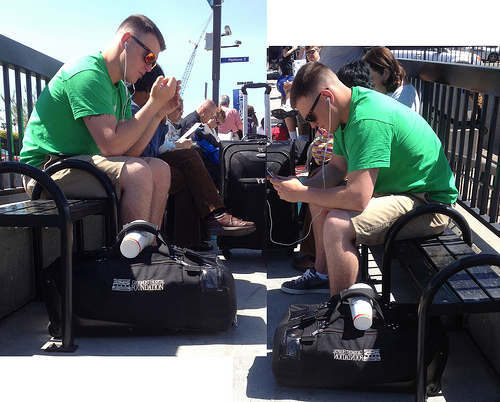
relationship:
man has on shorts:
[267, 59, 457, 321] [348, 185, 455, 247]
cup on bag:
[118, 219, 155, 258] [40, 220, 237, 336]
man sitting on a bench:
[268, 59, 458, 311] [359, 202, 498, 399]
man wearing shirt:
[268, 59, 458, 311] [322, 86, 463, 203]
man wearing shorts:
[268, 59, 458, 311] [340, 192, 452, 245]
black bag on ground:
[249, 288, 458, 400] [0, 216, 444, 400]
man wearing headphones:
[268, 59, 458, 311] [266, 92, 331, 249]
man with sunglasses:
[106, 45, 183, 86] [132, 38, 158, 69]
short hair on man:
[291, 58, 332, 110] [295, 64, 444, 337]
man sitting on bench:
[267, 59, 457, 321] [337, 168, 498, 400]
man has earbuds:
[19, 11, 182, 249] [120, 32, 130, 77]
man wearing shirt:
[19, 11, 182, 249] [20, 50, 138, 167]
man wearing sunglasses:
[19, 11, 182, 249] [121, 30, 160, 69]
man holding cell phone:
[267, 59, 457, 321] [267, 167, 279, 179]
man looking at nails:
[19, 11, 182, 249] [148, 71, 184, 121]